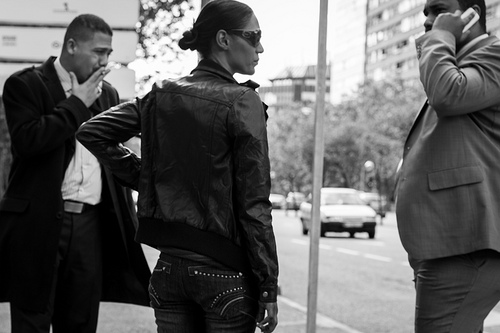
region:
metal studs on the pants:
[211, 285, 246, 312]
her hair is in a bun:
[181, 3, 253, 54]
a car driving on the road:
[301, 187, 375, 235]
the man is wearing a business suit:
[394, 0, 494, 331]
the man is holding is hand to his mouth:
[60, 14, 113, 107]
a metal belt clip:
[60, 200, 87, 216]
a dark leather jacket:
[76, 63, 281, 293]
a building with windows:
[362, 3, 423, 83]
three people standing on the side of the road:
[1, 3, 496, 328]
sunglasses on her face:
[228, 26, 265, 48]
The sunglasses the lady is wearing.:
[230, 20, 260, 41]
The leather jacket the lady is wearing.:
[82, 68, 292, 304]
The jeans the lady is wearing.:
[145, 245, 275, 331]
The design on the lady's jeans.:
[148, 270, 246, 317]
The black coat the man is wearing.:
[1, 49, 159, 317]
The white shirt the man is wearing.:
[53, 56, 98, 207]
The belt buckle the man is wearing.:
[64, 198, 84, 213]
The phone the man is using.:
[457, 9, 482, 31]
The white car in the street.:
[298, 186, 373, 238]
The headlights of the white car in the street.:
[326, 217, 378, 223]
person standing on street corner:
[9, 10, 129, 330]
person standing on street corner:
[174, 28, 256, 322]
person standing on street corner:
[393, 15, 489, 331]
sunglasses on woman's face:
[227, 30, 273, 50]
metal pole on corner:
[307, 10, 323, 324]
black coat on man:
[12, 74, 99, 313]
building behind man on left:
[2, 19, 149, 227]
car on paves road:
[311, 175, 376, 227]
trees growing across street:
[273, 74, 433, 206]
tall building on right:
[347, 14, 469, 220]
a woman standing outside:
[94, 26, 428, 279]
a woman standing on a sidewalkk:
[125, 14, 397, 321]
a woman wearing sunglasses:
[152, 13, 346, 293]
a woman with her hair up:
[137, 1, 282, 123]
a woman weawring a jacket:
[132, 5, 315, 282]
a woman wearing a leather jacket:
[110, 28, 393, 312]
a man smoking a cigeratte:
[34, 20, 132, 205]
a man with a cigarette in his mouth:
[22, 16, 169, 254]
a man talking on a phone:
[360, 20, 496, 237]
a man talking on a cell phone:
[412, 14, 495, 159]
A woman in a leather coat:
[75, 0, 282, 332]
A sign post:
[306, 0, 329, 332]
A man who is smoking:
[1, 13, 150, 331]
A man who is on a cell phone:
[393, 0, 498, 332]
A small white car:
[301, 185, 378, 237]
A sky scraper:
[362, 0, 498, 92]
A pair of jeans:
[148, 248, 258, 331]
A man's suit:
[396, 33, 498, 331]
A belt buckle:
[65, 199, 82, 214]